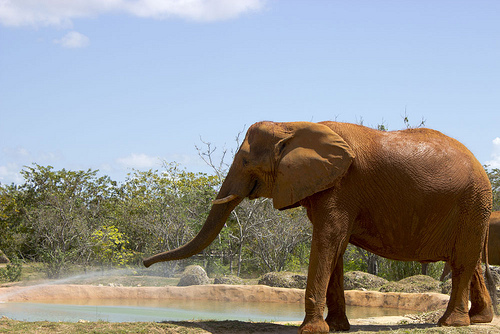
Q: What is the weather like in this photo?
A: It is clear.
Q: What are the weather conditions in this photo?
A: It is clear.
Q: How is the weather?
A: It is clear.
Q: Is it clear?
A: Yes, it is clear.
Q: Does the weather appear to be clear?
A: Yes, it is clear.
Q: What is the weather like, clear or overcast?
A: It is clear.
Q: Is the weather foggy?
A: No, it is clear.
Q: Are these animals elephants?
A: Yes, all the animals are elephants.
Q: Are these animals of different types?
A: No, all the animals are elephants.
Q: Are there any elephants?
A: Yes, there is an elephant.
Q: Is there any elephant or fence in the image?
A: Yes, there is an elephant.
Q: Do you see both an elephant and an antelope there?
A: No, there is an elephant but no antelopes.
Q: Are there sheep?
A: No, there are no sheep.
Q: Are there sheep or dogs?
A: No, there are no sheep or dogs.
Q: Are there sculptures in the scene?
A: No, there are no sculptures.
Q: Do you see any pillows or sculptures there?
A: No, there are no sculptures or pillows.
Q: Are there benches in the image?
A: No, there are no benches.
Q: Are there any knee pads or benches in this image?
A: No, there are no benches or knee pads.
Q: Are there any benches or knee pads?
A: No, there are no benches or knee pads.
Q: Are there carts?
A: No, there are no carts.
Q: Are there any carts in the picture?
A: No, there are no carts.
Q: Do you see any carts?
A: No, there are no carts.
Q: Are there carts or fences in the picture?
A: No, there are no carts or fences.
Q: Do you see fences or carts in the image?
A: No, there are no carts or fences.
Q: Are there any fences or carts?
A: No, there are no carts or fences.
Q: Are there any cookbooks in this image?
A: No, there are no cookbooks.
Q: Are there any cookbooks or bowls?
A: No, there are no cookbooks or bowls.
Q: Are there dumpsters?
A: No, there are no dumpsters.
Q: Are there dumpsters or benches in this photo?
A: No, there are no dumpsters or benches.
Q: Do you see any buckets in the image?
A: No, there are no buckets.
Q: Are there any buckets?
A: No, there are no buckets.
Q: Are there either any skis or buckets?
A: No, there are no buckets or skis.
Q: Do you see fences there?
A: No, there are no fences.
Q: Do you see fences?
A: No, there are no fences.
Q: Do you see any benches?
A: No, there are no benches.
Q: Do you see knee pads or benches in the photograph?
A: No, there are no benches or knee pads.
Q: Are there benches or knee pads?
A: No, there are no benches or knee pads.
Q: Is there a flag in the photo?
A: No, there are no flags.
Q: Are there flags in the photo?
A: No, there are no flags.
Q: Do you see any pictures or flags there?
A: No, there are no flags or pictures.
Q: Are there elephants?
A: Yes, there is an elephant.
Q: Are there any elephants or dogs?
A: Yes, there is an elephant.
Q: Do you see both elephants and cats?
A: No, there is an elephant but no cats.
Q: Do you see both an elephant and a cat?
A: No, there is an elephant but no cats.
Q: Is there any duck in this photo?
A: No, there are no ducks.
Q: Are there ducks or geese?
A: No, there are no ducks or geese.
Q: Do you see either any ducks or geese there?
A: No, there are no ducks or geese.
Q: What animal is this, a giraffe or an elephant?
A: This is an elephant.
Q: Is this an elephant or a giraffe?
A: This is an elephant.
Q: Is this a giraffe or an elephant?
A: This is an elephant.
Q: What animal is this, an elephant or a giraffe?
A: This is an elephant.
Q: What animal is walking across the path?
A: The elephant is walking across the path.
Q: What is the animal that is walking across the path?
A: The animal is an elephant.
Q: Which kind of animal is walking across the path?
A: The animal is an elephant.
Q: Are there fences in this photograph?
A: No, there are no fences.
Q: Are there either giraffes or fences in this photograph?
A: No, there are no fences or giraffes.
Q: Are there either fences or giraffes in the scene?
A: No, there are no fences or giraffes.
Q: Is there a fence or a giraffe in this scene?
A: No, there are no fences or giraffes.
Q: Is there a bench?
A: No, there are no benches.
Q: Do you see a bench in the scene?
A: No, there are no benches.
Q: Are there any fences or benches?
A: No, there are no benches or fences.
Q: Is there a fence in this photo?
A: No, there are no fences.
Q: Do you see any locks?
A: No, there are no locks.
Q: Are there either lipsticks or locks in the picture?
A: No, there are no locks or lipsticks.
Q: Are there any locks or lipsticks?
A: No, there are no locks or lipsticks.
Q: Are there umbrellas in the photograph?
A: No, there are no umbrellas.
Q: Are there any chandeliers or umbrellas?
A: No, there are no umbrellas or chandeliers.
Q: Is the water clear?
A: Yes, the water is clear.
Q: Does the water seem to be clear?
A: Yes, the water is clear.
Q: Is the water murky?
A: No, the water is clear.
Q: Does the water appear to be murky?
A: No, the water is clear.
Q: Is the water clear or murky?
A: The water is clear.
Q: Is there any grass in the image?
A: Yes, there is grass.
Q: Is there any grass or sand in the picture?
A: Yes, there is grass.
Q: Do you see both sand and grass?
A: No, there is grass but no sand.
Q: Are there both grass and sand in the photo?
A: No, there is grass but no sand.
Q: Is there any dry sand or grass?
A: Yes, there is dry grass.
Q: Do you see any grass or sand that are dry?
A: Yes, the grass is dry.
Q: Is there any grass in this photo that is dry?
A: Yes, there is dry grass.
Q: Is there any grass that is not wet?
A: Yes, there is dry grass.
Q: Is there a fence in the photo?
A: No, there are no fences.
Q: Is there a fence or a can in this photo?
A: No, there are no fences or cans.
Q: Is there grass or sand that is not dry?
A: No, there is grass but it is dry.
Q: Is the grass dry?
A: Yes, the grass is dry.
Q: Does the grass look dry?
A: Yes, the grass is dry.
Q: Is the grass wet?
A: No, the grass is dry.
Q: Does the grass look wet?
A: No, the grass is dry.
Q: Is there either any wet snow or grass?
A: No, there is grass but it is dry.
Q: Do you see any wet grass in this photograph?
A: No, there is grass but it is dry.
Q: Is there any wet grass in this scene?
A: No, there is grass but it is dry.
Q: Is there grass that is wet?
A: No, there is grass but it is dry.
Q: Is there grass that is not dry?
A: No, there is grass but it is dry.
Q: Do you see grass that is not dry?
A: No, there is grass but it is dry.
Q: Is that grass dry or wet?
A: The grass is dry.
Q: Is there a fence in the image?
A: No, there are no fences.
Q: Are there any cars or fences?
A: No, there are no fences or cars.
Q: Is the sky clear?
A: Yes, the sky is clear.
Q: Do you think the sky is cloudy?
A: No, the sky is clear.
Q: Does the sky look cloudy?
A: No, the sky is clear.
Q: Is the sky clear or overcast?
A: The sky is clear.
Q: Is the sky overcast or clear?
A: The sky is clear.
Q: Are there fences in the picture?
A: No, there are no fences.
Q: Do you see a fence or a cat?
A: No, there are no fences or cats.